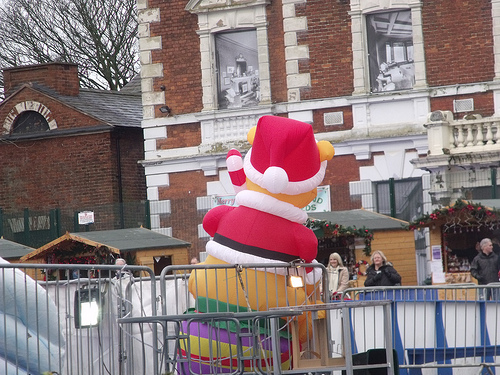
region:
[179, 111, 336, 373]
inflatable Santa Claus on the street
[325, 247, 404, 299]
two women across the street smiling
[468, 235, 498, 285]
man on street looking to his left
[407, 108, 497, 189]
balcony on front of building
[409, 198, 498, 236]
holly an lights on store front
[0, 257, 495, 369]
gates set up as a fence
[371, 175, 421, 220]
bars over lower window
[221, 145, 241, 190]
Santa holding a red and white candy cane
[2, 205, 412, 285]
small building sitting along the street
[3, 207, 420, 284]
light on the fence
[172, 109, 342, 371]
a large inflatable animal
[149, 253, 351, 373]
a large gray gate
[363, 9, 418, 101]
a window of a building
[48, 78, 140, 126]
the roof of a building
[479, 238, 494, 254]
the head of a man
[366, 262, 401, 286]
a woman's black jacket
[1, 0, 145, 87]
part of a large tree with no leaves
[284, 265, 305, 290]
a hanging outdoor light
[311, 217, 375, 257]
green Christmas decorations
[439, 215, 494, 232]
Christmas lights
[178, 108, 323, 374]
A blow up Christmas decoration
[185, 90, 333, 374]
A santa Christmas decoration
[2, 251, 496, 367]
Fencing at a Christmas display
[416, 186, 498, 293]
A shed with Christmas decorations on it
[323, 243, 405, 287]
Two woman standing near each other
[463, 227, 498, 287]
A man wearing a black jacket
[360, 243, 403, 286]
A woman wearing a black jacket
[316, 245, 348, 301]
A woman wearing a tan jacket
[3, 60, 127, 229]
An old brick building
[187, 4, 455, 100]
windows on an old building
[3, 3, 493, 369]
inflatable display and booths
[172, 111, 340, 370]
back of an inflatable display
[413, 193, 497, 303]
vending booth with vendor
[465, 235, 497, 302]
vendor looking towards street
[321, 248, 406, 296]
Two women viewing inflatable display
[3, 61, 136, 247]
dark red brick building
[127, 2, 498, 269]
light red brick building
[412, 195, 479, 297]
vending booth with Christmas decorations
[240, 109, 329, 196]
inflatable Santa hat on bear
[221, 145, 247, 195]
top of inflatable candy cane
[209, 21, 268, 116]
a window in a building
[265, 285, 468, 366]
a silver metal fence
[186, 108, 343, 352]
a blow up bear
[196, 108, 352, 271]
a blow up bear with a red hat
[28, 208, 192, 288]
a small brown building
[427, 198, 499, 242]
Christmas decorations on a building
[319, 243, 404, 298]
a couple watching the bear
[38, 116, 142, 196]
bricks on a building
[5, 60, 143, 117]
roof of a building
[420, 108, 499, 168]
wooden railing of a building